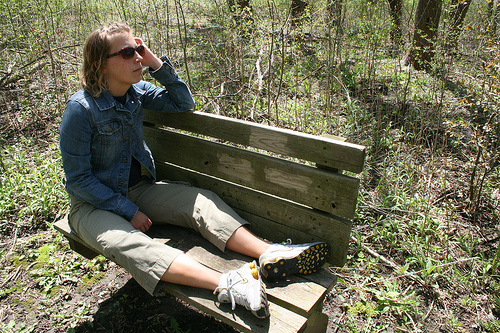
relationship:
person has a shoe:
[57, 21, 328, 318] [263, 241, 331, 285]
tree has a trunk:
[406, 2, 442, 70] [328, 0, 343, 29]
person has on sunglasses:
[57, 21, 328, 318] [103, 45, 145, 59]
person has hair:
[57, 21, 328, 318] [84, 23, 130, 98]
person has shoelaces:
[57, 21, 328, 318] [214, 277, 236, 312]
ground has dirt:
[1, 2, 499, 331] [80, 275, 108, 294]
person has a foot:
[57, 21, 328, 318] [219, 258, 269, 325]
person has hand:
[57, 21, 328, 318] [136, 38, 161, 70]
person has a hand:
[57, 21, 328, 318] [131, 212, 151, 233]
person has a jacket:
[57, 21, 328, 318] [57, 55, 194, 221]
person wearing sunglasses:
[57, 21, 328, 318] [103, 45, 145, 59]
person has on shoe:
[57, 21, 328, 318] [263, 241, 331, 285]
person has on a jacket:
[57, 21, 328, 318] [57, 55, 194, 221]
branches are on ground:
[250, 47, 266, 120] [1, 2, 499, 331]